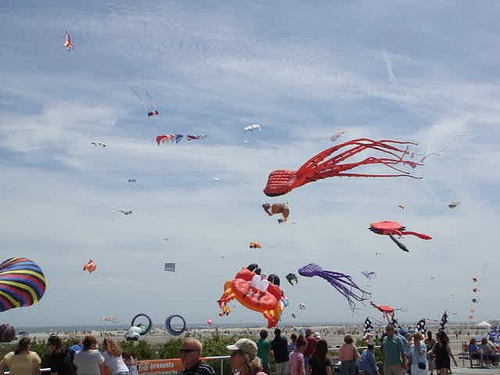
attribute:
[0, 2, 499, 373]
daytime scene — nice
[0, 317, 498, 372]
people — in white, in group,  different kind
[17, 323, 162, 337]
hills — far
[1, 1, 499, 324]
sky looks beautiful —  clear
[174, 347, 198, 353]
sunglasses —  man's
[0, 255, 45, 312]
multicolored stripes — multicolored 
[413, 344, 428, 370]
black purse —  black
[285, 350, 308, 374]
pink shirt —  pink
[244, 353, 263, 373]
long hair —  long,  woman's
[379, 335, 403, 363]
green shirt —  man's,  light green,  short sleeved,  blue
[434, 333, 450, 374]
dress is black —  black,  lady's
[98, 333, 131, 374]
woman — blonde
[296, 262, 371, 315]
purple kite — jellyfish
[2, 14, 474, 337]
kites — flown, beautiful, in air, for tournament, flying, crab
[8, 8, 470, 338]
sky — beautiful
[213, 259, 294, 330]
kite — large, crab shaped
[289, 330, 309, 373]
woman —  young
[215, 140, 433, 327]
objects —  Flying,  colored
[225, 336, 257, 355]
lid —  white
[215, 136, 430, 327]
balloons —  Different Colors,  flying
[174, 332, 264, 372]
friends — a couple,  talking